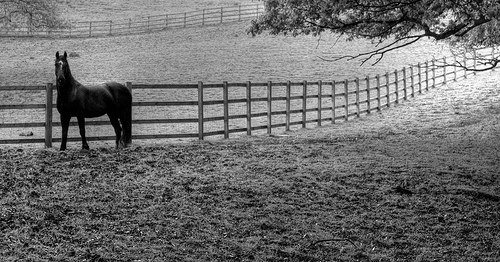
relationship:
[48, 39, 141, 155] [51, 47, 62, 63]
horse has ear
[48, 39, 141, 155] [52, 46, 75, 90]
horse has head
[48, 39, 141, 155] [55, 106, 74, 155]
horse has leg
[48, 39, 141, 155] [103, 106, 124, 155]
horse has leg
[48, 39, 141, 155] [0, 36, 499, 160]
horse by fence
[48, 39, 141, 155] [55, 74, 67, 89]
horse has nose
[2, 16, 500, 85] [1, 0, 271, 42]
field in fence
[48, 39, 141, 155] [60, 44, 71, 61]
horse has ear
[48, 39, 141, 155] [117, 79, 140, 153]
horse has tail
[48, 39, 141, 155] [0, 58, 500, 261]
horse on grass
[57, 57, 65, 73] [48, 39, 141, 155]
spot on horse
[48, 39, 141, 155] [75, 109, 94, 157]
horse has leg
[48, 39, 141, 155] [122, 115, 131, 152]
horse has leg